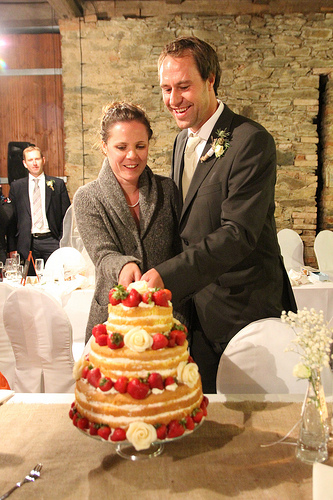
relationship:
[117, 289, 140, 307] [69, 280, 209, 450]
strawberry on cake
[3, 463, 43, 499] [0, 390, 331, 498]
fork on table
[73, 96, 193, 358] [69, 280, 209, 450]
woman cutting cake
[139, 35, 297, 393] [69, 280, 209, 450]
man cutting cake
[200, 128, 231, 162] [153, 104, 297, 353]
flower on coat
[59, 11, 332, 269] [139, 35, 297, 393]
stone wall behind man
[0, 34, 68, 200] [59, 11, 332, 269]
wood near stone wall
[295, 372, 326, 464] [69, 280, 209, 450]
vase next to cake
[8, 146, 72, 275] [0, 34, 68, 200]
man near wood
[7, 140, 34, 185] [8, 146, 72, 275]
speaker behind man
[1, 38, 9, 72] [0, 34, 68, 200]
light near wood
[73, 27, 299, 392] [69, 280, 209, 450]
couple cutting cake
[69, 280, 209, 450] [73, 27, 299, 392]
cake in front of couple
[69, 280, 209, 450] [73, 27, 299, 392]
cake getting cut by couple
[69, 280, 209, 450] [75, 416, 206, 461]
cake on a stand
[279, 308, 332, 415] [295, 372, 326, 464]
flowers in vase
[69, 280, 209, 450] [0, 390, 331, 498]
cake on table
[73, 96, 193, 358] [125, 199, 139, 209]
woman has a necklace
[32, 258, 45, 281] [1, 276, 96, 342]
glass on table